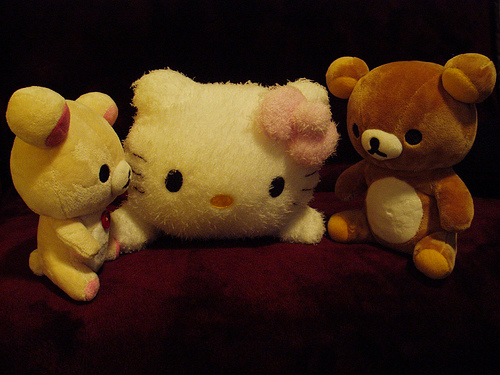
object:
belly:
[363, 175, 425, 243]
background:
[0, 1, 499, 205]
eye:
[402, 127, 426, 147]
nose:
[209, 193, 235, 209]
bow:
[258, 84, 342, 168]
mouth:
[206, 212, 239, 235]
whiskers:
[130, 152, 147, 163]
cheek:
[110, 117, 177, 231]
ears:
[132, 65, 197, 114]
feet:
[278, 204, 327, 246]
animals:
[319, 49, 494, 268]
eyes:
[351, 120, 362, 138]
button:
[100, 210, 113, 230]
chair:
[0, 244, 499, 374]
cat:
[113, 68, 340, 249]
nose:
[361, 129, 404, 162]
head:
[121, 102, 323, 240]